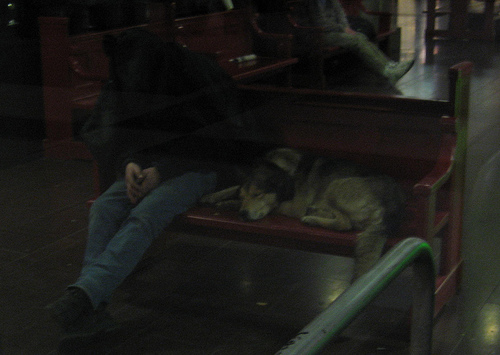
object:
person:
[299, 0, 415, 89]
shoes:
[388, 60, 418, 86]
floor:
[469, 81, 486, 261]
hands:
[124, 163, 143, 196]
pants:
[317, 29, 395, 75]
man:
[44, 27, 272, 333]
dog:
[199, 147, 412, 288]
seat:
[82, 60, 475, 321]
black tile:
[202, 248, 322, 294]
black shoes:
[46, 287, 91, 329]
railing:
[271, 239, 444, 355]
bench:
[35, 4, 402, 163]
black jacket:
[70, 28, 269, 198]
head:
[105, 26, 182, 110]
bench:
[63, 70, 471, 339]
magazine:
[229, 53, 258, 63]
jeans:
[64, 156, 218, 310]